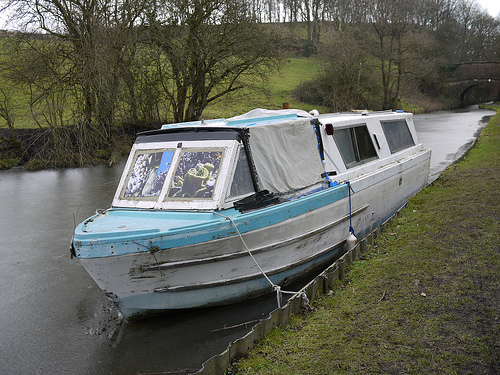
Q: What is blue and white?
A: The boat.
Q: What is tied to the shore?
A: A boat.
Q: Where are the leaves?
A: On the ground.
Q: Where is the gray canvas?
A: On the boat.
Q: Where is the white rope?
A: Tied to the boat.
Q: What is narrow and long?
A: The river bed.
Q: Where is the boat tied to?
A: The shore.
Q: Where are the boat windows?
A: In the front.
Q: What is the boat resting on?
A: Water.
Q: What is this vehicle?
A: Boat.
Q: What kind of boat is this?
A: Houseboat.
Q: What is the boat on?
A: Water.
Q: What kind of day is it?
A: Cloudy.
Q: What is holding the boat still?
A: Rope.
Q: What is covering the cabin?
A: Fabric.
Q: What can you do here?
A: Live.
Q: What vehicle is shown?
A: A boat.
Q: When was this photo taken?
A: During the day.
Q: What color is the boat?
A: White.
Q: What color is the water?
A: Gray.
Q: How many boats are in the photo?
A: One.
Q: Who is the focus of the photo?
A: The boat.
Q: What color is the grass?
A: Green.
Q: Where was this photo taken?
A: Near a river.